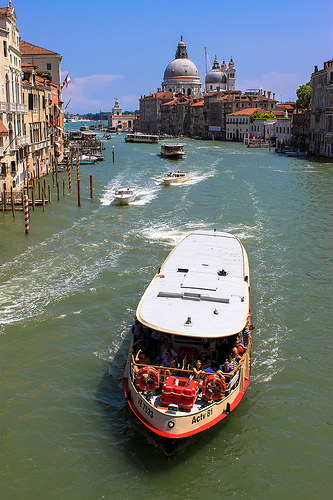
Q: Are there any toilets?
A: No, there are no toilets.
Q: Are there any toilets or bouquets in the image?
A: No, there are no toilets or bouquets.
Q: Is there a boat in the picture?
A: Yes, there is a boat.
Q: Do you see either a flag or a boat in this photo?
A: Yes, there is a boat.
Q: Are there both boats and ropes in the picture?
A: No, there is a boat but no ropes.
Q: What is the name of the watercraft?
A: The watercraft is a boat.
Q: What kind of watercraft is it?
A: The watercraft is a boat.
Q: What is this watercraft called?
A: This is a boat.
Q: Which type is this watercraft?
A: This is a boat.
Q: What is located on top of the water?
A: The boat is on top of the water.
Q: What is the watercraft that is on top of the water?
A: The watercraft is a boat.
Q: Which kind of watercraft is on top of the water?
A: The watercraft is a boat.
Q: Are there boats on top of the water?
A: Yes, there is a boat on top of the water.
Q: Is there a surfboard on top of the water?
A: No, there is a boat on top of the water.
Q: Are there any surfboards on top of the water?
A: No, there is a boat on top of the water.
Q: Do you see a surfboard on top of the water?
A: No, there is a boat on top of the water.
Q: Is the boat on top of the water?
A: Yes, the boat is on top of the water.